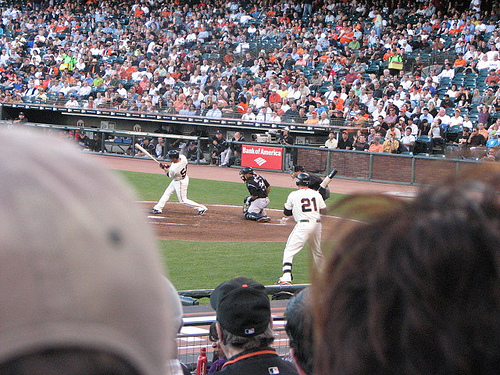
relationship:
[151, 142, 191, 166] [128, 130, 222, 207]
helmet on player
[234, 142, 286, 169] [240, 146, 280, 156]
sign has letters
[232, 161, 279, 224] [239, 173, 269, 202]
catcher wearing shirt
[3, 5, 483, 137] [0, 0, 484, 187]
fans in bleachers